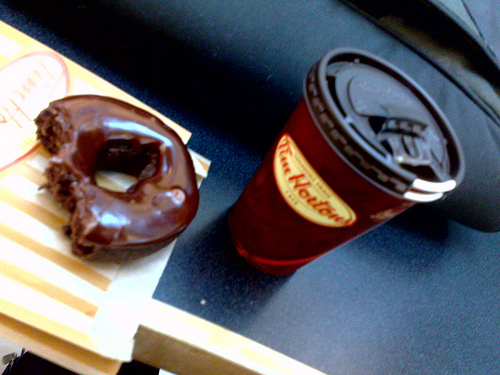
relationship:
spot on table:
[197, 296, 207, 306] [21, 15, 492, 324]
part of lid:
[404, 176, 455, 204] [304, 45, 465, 203]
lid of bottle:
[390, 159, 452, 189] [226, 45, 466, 278]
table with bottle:
[279, 216, 496, 373] [226, 45, 466, 278]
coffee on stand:
[222, 40, 468, 277] [59, 48, 486, 372]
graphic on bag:
[3, 44, 75, 178] [1, 7, 219, 370]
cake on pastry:
[34, 94, 199, 263] [33, 90, 201, 260]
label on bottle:
[270, 132, 355, 232] [226, 45, 466, 278]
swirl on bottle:
[236, 246, 313, 268] [226, 45, 466, 278]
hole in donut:
[71, 120, 166, 209] [23, 79, 203, 259]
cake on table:
[34, 94, 199, 263] [155, 284, 475, 349]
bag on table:
[1, 7, 219, 370] [0, 4, 499, 372]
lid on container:
[304, 46, 467, 203] [221, 42, 466, 277]